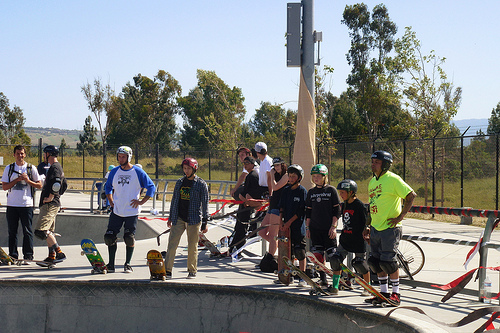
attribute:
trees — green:
[0, 4, 498, 177]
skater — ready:
[80, 146, 157, 274]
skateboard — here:
[79, 235, 109, 274]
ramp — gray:
[1, 281, 418, 333]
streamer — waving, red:
[431, 266, 481, 290]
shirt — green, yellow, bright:
[366, 169, 416, 234]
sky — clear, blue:
[1, 1, 498, 129]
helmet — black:
[369, 149, 393, 163]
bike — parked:
[358, 224, 426, 285]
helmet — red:
[182, 157, 200, 171]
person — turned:
[33, 146, 70, 271]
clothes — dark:
[304, 185, 341, 254]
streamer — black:
[441, 274, 472, 304]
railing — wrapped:
[403, 205, 499, 223]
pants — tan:
[164, 217, 202, 279]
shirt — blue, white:
[104, 163, 158, 219]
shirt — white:
[258, 154, 274, 188]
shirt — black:
[274, 184, 308, 242]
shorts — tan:
[34, 202, 59, 234]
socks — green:
[330, 274, 341, 290]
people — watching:
[2, 142, 418, 310]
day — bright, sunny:
[2, 1, 488, 136]